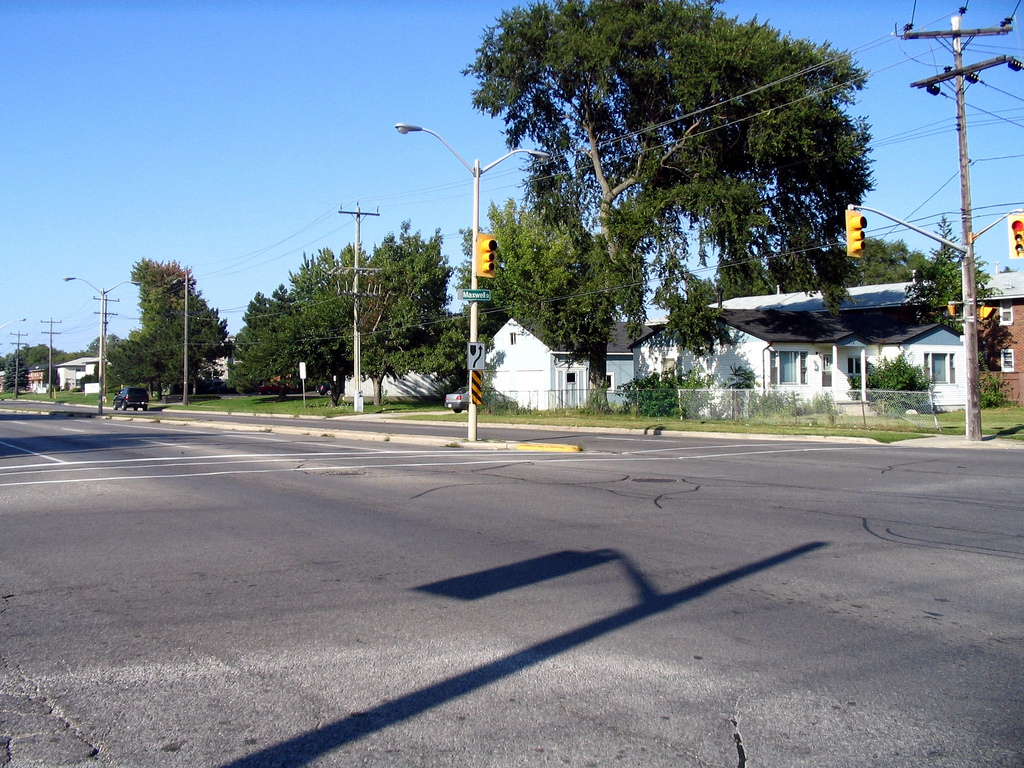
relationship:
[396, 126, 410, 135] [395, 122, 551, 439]
light attached to street light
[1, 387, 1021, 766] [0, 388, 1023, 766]
shadows on ground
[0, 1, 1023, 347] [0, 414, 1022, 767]
wires above ground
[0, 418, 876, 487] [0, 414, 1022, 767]
lines on ground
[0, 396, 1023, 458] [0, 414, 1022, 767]
curb on ground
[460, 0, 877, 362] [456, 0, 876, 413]
leaves on tree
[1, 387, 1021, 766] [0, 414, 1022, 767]
shadows on ground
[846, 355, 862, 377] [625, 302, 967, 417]
window on house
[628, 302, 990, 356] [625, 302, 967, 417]
rooftop of house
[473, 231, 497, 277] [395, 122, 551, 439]
traffic light casing on street light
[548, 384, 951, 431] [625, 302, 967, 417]
fence in front of house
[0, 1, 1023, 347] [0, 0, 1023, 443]
wires hanging from poles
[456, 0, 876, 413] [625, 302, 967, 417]
tree in front of house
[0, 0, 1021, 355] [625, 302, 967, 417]
sky above house